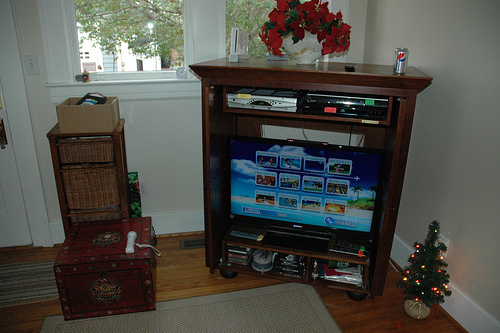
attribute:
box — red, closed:
[53, 203, 159, 323]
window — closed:
[41, 4, 207, 95]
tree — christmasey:
[397, 212, 457, 324]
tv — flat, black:
[217, 133, 384, 250]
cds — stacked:
[227, 245, 307, 279]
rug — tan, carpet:
[48, 286, 334, 331]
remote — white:
[120, 223, 147, 261]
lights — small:
[409, 242, 425, 272]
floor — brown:
[156, 235, 201, 294]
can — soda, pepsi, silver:
[387, 42, 415, 83]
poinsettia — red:
[266, 7, 345, 43]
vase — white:
[282, 35, 323, 64]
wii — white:
[227, 24, 248, 66]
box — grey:
[223, 89, 300, 111]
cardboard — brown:
[56, 89, 123, 136]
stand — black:
[252, 224, 345, 257]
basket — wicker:
[62, 166, 121, 211]